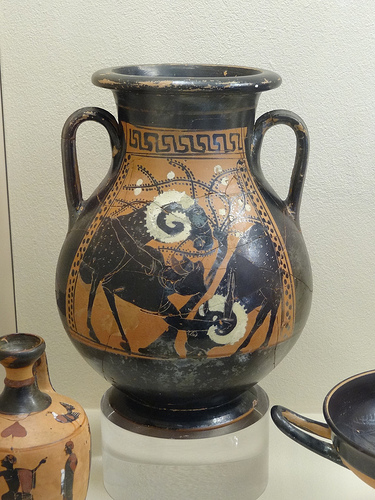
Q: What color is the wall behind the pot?
A: White.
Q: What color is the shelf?
A: White.